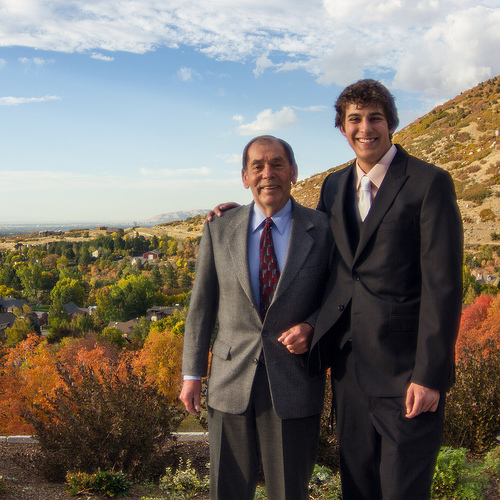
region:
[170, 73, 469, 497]
tow men in suits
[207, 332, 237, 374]
pocket on the suit jacket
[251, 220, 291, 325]
tie hanging down the torso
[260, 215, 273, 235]
knot at the top of the tie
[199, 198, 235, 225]
hand resting on the shoulder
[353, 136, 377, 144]
smile on the face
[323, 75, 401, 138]
dark curly hair on the head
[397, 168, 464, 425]
arm laying down by the side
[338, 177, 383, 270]
tie is partially hidden by the suit jacket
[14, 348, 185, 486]
small bush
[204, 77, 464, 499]
A taller man with curly dark brown hair in a suit.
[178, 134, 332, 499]
Older man in a grey suit.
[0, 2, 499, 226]
Blue and white sky.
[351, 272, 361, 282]
Top black button on a black jacket that is buttoned.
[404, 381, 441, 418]
A man's left hand coming out of a black suit.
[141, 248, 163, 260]
A long red barn with a large white door.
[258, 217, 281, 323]
A red and grey tie on a man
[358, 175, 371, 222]
A solid white tie.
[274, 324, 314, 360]
Man in a grey suit's left hand.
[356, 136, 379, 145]
Toothy smile of a curly brown haired man.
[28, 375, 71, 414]
fall tree on hill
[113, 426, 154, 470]
fall tree on hill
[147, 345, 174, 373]
fall tree on hill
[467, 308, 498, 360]
fall tree on hill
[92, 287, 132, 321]
fall tree on hill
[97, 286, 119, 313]
fall tree on hill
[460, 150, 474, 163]
fall tree on hill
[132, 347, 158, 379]
fall tree on hill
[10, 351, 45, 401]
fall tree on hill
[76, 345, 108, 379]
fall tree on hill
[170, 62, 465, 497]
Two men in the foreground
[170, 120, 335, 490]
Older man is wearing a gray suit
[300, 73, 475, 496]
Younger man is wearing a black suit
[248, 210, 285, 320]
Man is wearing a red tie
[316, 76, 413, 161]
Young man has dark brown hair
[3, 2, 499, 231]
White clouds in the sky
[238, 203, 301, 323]
Man is wearing a blue dress shirt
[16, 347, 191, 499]
A brown bush in the foreground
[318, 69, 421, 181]
Young man is smiling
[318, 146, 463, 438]
jacket is worn by human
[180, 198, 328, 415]
jacket is worn by human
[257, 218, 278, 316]
tie is worn by human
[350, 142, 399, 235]
button down shirt is worn by human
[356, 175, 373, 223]
tie is worn by human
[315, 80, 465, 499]
human wears suit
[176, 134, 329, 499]
human wears suit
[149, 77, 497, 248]
mountain is in background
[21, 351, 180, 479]
plant is behind old man